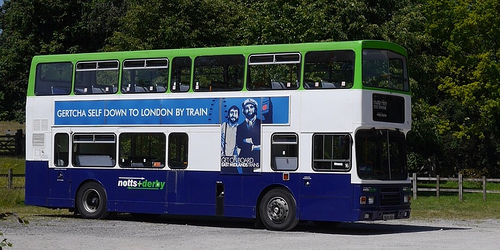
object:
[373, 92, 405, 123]
window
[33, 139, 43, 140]
vents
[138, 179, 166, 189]
words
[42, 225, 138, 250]
ground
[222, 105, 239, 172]
men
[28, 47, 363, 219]
side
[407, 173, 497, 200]
fence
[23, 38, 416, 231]
bus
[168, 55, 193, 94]
windows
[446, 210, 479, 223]
ground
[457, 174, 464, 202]
wooden fence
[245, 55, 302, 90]
windows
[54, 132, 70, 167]
windows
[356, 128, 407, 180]
front window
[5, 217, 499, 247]
road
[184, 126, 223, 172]
white tiles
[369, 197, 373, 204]
light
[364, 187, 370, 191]
light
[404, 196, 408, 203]
light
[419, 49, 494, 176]
trees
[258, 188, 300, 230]
black tire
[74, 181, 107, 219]
black tire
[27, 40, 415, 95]
bus top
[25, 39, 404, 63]
deck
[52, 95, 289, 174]
advertisement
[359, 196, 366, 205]
headlights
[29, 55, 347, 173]
two floors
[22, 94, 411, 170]
middle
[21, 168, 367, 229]
bottom